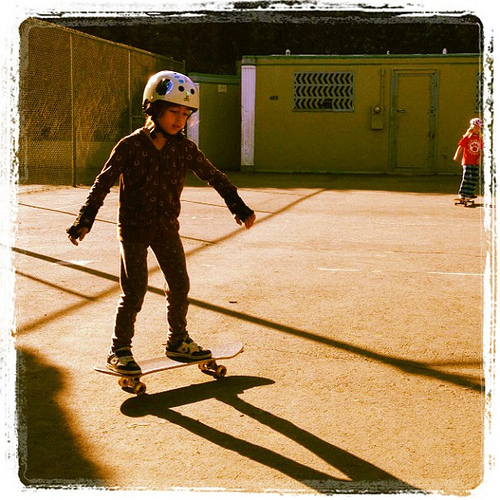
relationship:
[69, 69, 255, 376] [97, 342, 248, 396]
girl on top of skateboard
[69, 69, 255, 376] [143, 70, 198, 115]
girl wearing helmet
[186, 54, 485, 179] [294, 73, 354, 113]
building has window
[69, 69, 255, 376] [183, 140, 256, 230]
girl has left arm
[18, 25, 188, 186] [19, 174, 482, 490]
fence on top of asphalt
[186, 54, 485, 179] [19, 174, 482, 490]
building on top of asphalt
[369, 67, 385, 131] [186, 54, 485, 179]
gas meter hanging on building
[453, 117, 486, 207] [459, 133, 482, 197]
child has outfit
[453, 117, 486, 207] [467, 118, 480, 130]
child wearing helmet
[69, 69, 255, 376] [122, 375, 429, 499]
girl has shadow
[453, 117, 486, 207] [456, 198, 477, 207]
child riding skateboard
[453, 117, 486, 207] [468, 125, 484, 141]
child has hair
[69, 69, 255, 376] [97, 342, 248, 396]
girl riding skateboard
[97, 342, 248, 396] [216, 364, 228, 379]
skateboard has wheel